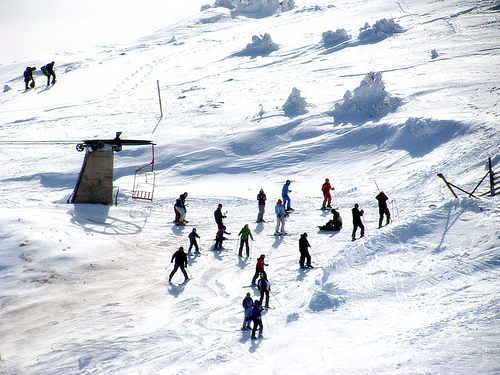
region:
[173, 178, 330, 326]
Skiers on the snow.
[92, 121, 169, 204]
Sky lift is red.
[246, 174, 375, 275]
People are skiing.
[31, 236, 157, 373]
Snow is on the ground.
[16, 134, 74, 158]
Wires to the sky lift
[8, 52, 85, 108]
People walking up the hill.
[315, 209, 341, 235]
Person sitting on the snow.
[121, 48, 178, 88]
Foot prints in the snow.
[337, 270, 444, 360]
The snow is white.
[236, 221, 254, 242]
Person wearing green jacket.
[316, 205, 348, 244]
the person sitting down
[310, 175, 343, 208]
the person in a red snowsuit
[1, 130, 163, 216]
the ski lift appears broken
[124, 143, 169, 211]
the ski lift chair is red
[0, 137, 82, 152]
the cables of the ski lift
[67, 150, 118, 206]
the concrete base of the ski lift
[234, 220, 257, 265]
the person in the green jacket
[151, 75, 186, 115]
the pole in the snow above the ski lift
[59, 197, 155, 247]
the shadow of the ski lift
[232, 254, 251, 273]
the shadow of the person in the green jacket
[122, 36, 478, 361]
people are skiing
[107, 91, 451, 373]
people skiing on the snow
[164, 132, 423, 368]
group of people skiing on the snow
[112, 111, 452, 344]
people skiing on the white snow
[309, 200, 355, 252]
a person sitting on the snow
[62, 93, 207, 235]
a ski lift over the snow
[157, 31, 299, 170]
ground covered in white snwo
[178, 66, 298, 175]
ground covered in snow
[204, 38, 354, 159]
white snow covering the ground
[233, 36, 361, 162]
snow covering the ground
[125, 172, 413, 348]
people learning to ski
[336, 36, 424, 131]
snow bergs forming in the snow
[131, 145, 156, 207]
a red ski lift chair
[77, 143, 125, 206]
a stone support in the snow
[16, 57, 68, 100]
two people hiking up the hill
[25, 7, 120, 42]
a bright white sky overhead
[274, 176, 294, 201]
a person wearing a blue ski suite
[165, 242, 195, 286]
a person standing with inverted legs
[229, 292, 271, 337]
two people chatting with each other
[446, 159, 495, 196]
a wooden fence in the snow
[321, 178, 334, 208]
skier wearing a red outfit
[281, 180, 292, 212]
skier wearing a blue outfit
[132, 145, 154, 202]
red ski lift chair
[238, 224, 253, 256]
skier wearing a green outfit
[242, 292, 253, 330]
skier wearing a blue and black outfit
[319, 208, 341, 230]
skier taking a break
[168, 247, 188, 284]
skier using technique to control speed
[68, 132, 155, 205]
grey concrete and metal ski lift endpoint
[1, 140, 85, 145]
black metal ski lift cable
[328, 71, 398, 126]
large white snow pile